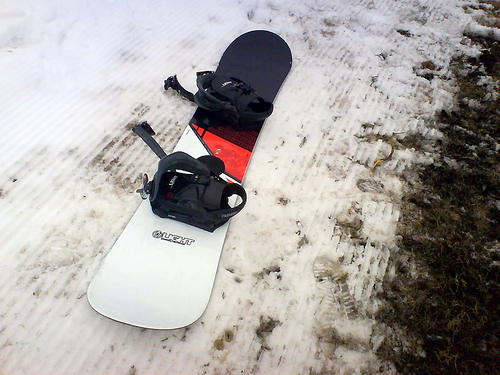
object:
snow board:
[86, 29, 294, 331]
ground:
[0, 0, 499, 374]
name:
[160, 232, 195, 246]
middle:
[170, 106, 265, 187]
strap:
[161, 73, 200, 106]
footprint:
[354, 176, 419, 215]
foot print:
[332, 207, 366, 265]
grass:
[0, 0, 498, 374]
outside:
[0, 0, 498, 374]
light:
[158, 231, 193, 247]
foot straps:
[194, 70, 274, 122]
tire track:
[1, 0, 479, 373]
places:
[134, 152, 247, 233]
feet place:
[148, 151, 248, 233]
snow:
[0, 0, 499, 374]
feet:
[309, 256, 358, 321]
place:
[191, 71, 272, 124]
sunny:
[0, 0, 499, 374]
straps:
[131, 121, 168, 159]